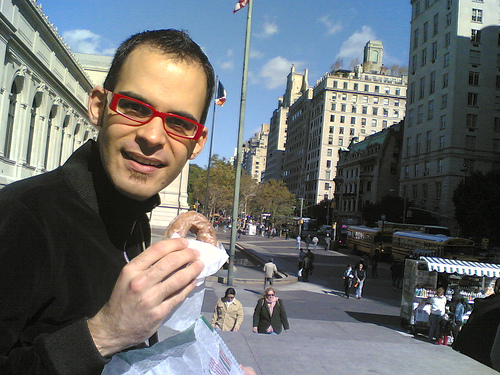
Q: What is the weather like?
A: It is partly cloudy.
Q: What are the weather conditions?
A: It is partly cloudy.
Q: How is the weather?
A: It is partly cloudy.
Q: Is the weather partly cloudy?
A: Yes, it is partly cloudy.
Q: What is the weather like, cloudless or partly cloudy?
A: It is partly cloudy.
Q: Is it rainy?
A: No, it is partly cloudy.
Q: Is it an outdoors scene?
A: Yes, it is outdoors.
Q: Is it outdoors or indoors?
A: It is outdoors.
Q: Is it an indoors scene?
A: No, it is outdoors.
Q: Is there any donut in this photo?
A: Yes, there is a donut.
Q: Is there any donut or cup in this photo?
A: Yes, there is a donut.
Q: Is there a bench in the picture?
A: No, there are no benches.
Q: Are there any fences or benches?
A: No, there are no benches or fences.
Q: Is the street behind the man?
A: Yes, the street is behind the man.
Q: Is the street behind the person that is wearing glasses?
A: Yes, the street is behind the man.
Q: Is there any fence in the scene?
A: No, there are no fences.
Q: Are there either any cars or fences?
A: No, there are no fences or cars.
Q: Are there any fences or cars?
A: No, there are no fences or cars.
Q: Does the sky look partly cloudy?
A: Yes, the sky is partly cloudy.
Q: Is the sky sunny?
A: No, the sky is partly cloudy.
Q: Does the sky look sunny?
A: No, the sky is partly cloudy.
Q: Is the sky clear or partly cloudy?
A: The sky is partly cloudy.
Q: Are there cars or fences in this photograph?
A: No, there are no fences or cars.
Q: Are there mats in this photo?
A: No, there are no mats.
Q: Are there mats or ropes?
A: No, there are no mats or ropes.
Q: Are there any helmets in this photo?
A: No, there are no helmets.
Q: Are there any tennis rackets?
A: No, there are no tennis rackets.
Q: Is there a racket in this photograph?
A: No, there are no rackets.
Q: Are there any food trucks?
A: Yes, there is a food truck.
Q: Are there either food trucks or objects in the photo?
A: Yes, there is a food truck.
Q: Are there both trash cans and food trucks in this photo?
A: No, there is a food truck but no trash cans.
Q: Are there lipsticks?
A: No, there are no lipsticks.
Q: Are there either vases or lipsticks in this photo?
A: No, there are no lipsticks or vases.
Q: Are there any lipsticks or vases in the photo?
A: No, there are no lipsticks or vases.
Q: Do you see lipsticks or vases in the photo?
A: No, there are no lipsticks or vases.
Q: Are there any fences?
A: No, there are no fences.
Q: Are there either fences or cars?
A: No, there are no fences or cars.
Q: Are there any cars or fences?
A: No, there are no fences or cars.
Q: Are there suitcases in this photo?
A: No, there are no suitcases.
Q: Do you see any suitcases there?
A: No, there are no suitcases.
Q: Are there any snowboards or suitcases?
A: No, there are no suitcases or snowboards.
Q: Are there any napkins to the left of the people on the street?
A: Yes, there is a napkin to the left of the people.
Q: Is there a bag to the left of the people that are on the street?
A: No, there is a napkin to the left of the people.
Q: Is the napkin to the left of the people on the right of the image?
A: Yes, the napkin is to the left of the people.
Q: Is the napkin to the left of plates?
A: No, the napkin is to the left of the people.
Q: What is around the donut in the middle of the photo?
A: The napkin is around the donut.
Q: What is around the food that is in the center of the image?
A: The napkin is around the donut.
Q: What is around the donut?
A: The napkin is around the donut.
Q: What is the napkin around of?
A: The napkin is around the donut.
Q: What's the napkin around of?
A: The napkin is around the donut.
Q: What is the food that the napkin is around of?
A: The food is a donut.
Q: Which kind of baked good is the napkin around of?
A: The napkin is around the donut.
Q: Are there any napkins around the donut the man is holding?
A: Yes, there is a napkin around the doughnut.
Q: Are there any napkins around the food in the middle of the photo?
A: Yes, there is a napkin around the doughnut.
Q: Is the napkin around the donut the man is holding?
A: Yes, the napkin is around the doughnut.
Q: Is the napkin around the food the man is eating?
A: Yes, the napkin is around the doughnut.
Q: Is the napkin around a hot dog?
A: No, the napkin is around the doughnut.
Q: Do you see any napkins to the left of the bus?
A: Yes, there is a napkin to the left of the bus.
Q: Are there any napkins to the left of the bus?
A: Yes, there is a napkin to the left of the bus.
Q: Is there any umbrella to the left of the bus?
A: No, there is a napkin to the left of the bus.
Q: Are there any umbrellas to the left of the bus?
A: No, there is a napkin to the left of the bus.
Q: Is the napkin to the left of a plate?
A: No, the napkin is to the left of the bus.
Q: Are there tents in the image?
A: No, there are no tents.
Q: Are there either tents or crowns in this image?
A: No, there are no tents or crowns.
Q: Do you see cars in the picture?
A: No, there are no cars.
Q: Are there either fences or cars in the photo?
A: No, there are no cars or fences.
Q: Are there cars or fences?
A: No, there are no cars or fences.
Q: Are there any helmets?
A: No, there are no helmets.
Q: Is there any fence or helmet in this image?
A: No, there are no helmets or fences.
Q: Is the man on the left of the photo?
A: Yes, the man is on the left of the image.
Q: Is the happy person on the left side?
A: Yes, the man is on the left of the image.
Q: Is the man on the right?
A: No, the man is on the left of the image.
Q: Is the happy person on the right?
A: No, the man is on the left of the image.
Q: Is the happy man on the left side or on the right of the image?
A: The man is on the left of the image.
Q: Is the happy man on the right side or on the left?
A: The man is on the left of the image.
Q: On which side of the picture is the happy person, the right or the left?
A: The man is on the left of the image.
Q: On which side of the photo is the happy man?
A: The man is on the left of the image.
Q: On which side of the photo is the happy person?
A: The man is on the left of the image.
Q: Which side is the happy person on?
A: The man is on the left of the image.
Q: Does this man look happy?
A: Yes, the man is happy.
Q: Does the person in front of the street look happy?
A: Yes, the man is happy.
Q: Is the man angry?
A: No, the man is happy.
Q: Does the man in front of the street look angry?
A: No, the man is happy.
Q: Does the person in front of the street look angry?
A: No, the man is happy.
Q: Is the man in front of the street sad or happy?
A: The man is happy.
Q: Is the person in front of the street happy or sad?
A: The man is happy.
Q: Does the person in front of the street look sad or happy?
A: The man is happy.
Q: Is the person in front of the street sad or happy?
A: The man is happy.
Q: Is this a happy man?
A: Yes, this is a happy man.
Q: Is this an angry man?
A: No, this is a happy man.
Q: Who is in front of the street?
A: The man is in front of the street.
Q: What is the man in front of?
A: The man is in front of the street.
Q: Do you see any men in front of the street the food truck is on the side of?
A: Yes, there is a man in front of the street.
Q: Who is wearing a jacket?
A: The man is wearing a jacket.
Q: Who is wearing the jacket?
A: The man is wearing a jacket.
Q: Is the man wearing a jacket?
A: Yes, the man is wearing a jacket.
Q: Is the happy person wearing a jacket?
A: Yes, the man is wearing a jacket.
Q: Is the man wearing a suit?
A: No, the man is wearing a jacket.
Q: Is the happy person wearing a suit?
A: No, the man is wearing a jacket.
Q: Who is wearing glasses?
A: The man is wearing glasses.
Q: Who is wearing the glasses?
A: The man is wearing glasses.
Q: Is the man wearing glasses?
A: Yes, the man is wearing glasses.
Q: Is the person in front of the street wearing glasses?
A: Yes, the man is wearing glasses.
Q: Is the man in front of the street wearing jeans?
A: No, the man is wearing glasses.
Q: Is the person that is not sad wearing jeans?
A: No, the man is wearing glasses.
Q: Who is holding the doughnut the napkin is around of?
A: The man is holding the doughnut.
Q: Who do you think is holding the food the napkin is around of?
A: The man is holding the doughnut.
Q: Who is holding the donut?
A: The man is holding the doughnut.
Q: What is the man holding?
A: The man is holding the doughnut.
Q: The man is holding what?
A: The man is holding the doughnut.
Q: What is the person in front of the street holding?
A: The man is holding the doughnut.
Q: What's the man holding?
A: The man is holding the doughnut.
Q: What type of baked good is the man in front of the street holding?
A: The man is holding the doughnut.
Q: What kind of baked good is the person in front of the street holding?
A: The man is holding the doughnut.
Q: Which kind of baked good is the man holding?
A: The man is holding the doughnut.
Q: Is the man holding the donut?
A: Yes, the man is holding the donut.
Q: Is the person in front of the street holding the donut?
A: Yes, the man is holding the donut.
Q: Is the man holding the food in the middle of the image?
A: Yes, the man is holding the donut.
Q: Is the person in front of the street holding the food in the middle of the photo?
A: Yes, the man is holding the donut.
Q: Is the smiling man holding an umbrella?
A: No, the man is holding the donut.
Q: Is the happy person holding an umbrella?
A: No, the man is holding the donut.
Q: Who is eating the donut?
A: The man is eating the donut.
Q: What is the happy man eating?
A: The man is eating a doughnut.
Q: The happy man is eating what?
A: The man is eating a doughnut.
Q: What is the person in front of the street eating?
A: The man is eating a doughnut.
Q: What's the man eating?
A: The man is eating a doughnut.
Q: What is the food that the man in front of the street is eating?
A: The food is a donut.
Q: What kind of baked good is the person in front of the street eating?
A: The man is eating a doughnut.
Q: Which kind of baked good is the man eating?
A: The man is eating a doughnut.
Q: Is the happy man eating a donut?
A: Yes, the man is eating a donut.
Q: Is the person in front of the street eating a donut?
A: Yes, the man is eating a donut.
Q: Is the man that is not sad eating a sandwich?
A: No, the man is eating a donut.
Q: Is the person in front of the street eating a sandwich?
A: No, the man is eating a donut.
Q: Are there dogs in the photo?
A: No, there are no dogs.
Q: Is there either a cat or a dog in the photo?
A: No, there are no dogs or cats.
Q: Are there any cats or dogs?
A: No, there are no dogs or cats.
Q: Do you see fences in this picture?
A: No, there are no fences.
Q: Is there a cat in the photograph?
A: No, there are no cats.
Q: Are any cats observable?
A: No, there are no cats.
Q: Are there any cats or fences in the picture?
A: No, there are no cats or fences.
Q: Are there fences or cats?
A: No, there are no cats or fences.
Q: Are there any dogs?
A: No, there are no dogs.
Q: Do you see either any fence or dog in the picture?
A: No, there are no dogs or fences.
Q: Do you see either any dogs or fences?
A: No, there are no dogs or fences.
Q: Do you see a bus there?
A: Yes, there is a bus.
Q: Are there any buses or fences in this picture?
A: Yes, there is a bus.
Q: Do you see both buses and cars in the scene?
A: No, there is a bus but no cars.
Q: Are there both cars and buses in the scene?
A: No, there is a bus but no cars.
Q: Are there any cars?
A: No, there are no cars.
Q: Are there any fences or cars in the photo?
A: No, there are no cars or fences.